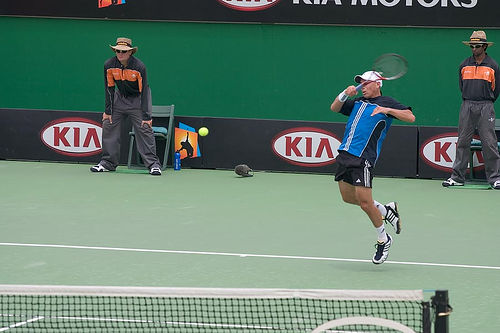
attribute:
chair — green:
[116, 98, 177, 179]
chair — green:
[454, 112, 496, 194]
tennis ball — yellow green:
[199, 126, 209, 138]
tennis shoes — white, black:
[368, 198, 404, 268]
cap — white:
[352, 67, 384, 93]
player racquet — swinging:
[318, 48, 427, 278]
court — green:
[0, 158, 499, 331]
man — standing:
[82, 32, 174, 177]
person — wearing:
[308, 79, 452, 221]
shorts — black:
[328, 146, 408, 214]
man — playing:
[327, 60, 417, 271]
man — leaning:
[90, 34, 163, 175]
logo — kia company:
[264, 123, 341, 173]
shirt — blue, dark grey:
[333, 95, 398, 165]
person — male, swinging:
[331, 65, 420, 266]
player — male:
[328, 71, 418, 264]